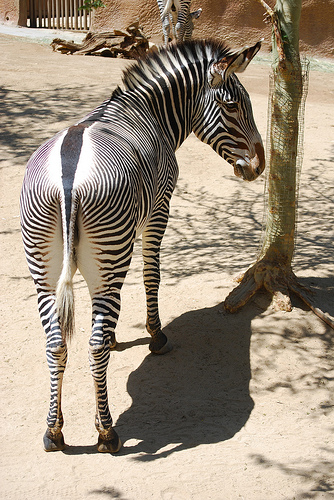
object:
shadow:
[60, 239, 292, 462]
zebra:
[20, 35, 269, 455]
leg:
[142, 208, 170, 338]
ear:
[229, 40, 261, 77]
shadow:
[87, 477, 128, 499]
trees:
[222, 0, 333, 326]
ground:
[0, 32, 334, 499]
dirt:
[1, 30, 334, 499]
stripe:
[60, 93, 114, 254]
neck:
[142, 57, 208, 154]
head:
[180, 7, 204, 43]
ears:
[206, 49, 245, 89]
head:
[190, 39, 266, 184]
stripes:
[221, 146, 249, 166]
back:
[18, 102, 157, 297]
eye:
[222, 99, 239, 111]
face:
[192, 69, 266, 184]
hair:
[115, 37, 227, 94]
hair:
[55, 277, 76, 344]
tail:
[52, 181, 81, 344]